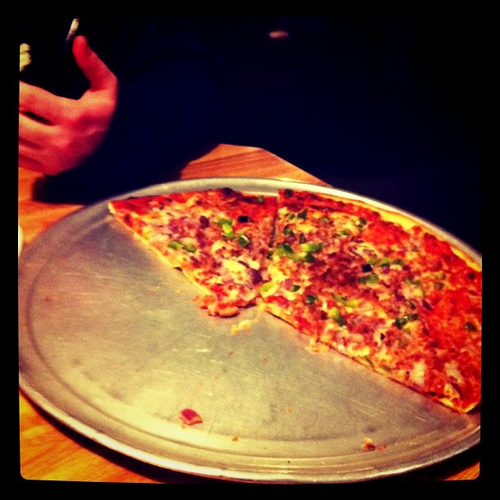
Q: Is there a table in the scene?
A: Yes, there is a table.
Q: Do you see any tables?
A: Yes, there is a table.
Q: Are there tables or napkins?
A: Yes, there is a table.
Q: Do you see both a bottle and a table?
A: No, there is a table but no bottles.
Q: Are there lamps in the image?
A: No, there are no lamps.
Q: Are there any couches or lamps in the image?
A: No, there are no lamps or couches.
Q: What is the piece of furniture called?
A: The piece of furniture is a table.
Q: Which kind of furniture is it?
A: The piece of furniture is a table.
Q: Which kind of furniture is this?
A: This is a table.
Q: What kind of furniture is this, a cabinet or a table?
A: This is a table.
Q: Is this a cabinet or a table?
A: This is a table.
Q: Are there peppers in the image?
A: Yes, there are peppers.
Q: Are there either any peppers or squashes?
A: Yes, there are peppers.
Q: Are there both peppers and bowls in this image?
A: No, there are peppers but no bowls.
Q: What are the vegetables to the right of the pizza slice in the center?
A: The vegetables are peppers.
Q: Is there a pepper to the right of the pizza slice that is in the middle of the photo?
A: Yes, there are peppers to the right of the pizza slice.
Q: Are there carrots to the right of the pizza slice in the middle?
A: No, there are peppers to the right of the pizza slice.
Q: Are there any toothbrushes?
A: No, there are no toothbrushes.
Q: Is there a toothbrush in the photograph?
A: No, there are no toothbrushes.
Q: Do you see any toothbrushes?
A: No, there are no toothbrushes.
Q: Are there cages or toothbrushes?
A: No, there are no toothbrushes or cages.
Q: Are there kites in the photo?
A: No, there are no kites.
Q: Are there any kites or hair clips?
A: No, there are no kites or hair clips.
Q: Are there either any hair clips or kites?
A: No, there are no kites or hair clips.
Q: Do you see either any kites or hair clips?
A: No, there are no kites or hair clips.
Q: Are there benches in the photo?
A: No, there are no benches.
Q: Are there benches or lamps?
A: No, there are no benches or lamps.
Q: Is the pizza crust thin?
A: Yes, the pizza crust is thin.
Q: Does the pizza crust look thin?
A: Yes, the pizza crust is thin.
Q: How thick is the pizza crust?
A: The pizza crust is thin.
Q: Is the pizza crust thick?
A: No, the pizza crust is thin.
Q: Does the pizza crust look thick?
A: No, the pizza crust is thin.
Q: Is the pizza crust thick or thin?
A: The pizza crust is thin.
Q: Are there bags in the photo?
A: No, there are no bags.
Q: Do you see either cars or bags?
A: No, there are no bags or cars.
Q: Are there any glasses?
A: No, there are no glasses.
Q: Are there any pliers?
A: No, there are no pliers.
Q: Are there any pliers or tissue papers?
A: No, there are no pliers or tissue papers.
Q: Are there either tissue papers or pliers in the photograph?
A: No, there are no pliers or tissue papers.